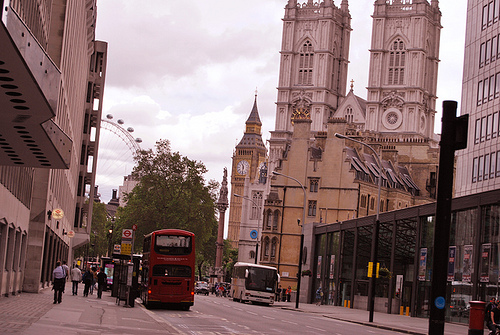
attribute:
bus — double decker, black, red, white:
[139, 227, 198, 316]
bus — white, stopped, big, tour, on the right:
[228, 260, 283, 311]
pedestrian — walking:
[49, 260, 67, 305]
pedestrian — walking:
[95, 265, 109, 299]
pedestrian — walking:
[69, 261, 83, 296]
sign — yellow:
[364, 258, 382, 281]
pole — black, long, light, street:
[366, 220, 385, 326]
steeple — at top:
[349, 78, 356, 90]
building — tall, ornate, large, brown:
[232, 1, 465, 301]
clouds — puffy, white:
[145, 57, 269, 114]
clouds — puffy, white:
[96, 83, 170, 124]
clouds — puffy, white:
[86, 106, 276, 190]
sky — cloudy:
[79, 0, 471, 240]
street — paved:
[107, 276, 424, 334]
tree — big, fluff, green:
[110, 139, 231, 291]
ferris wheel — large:
[81, 110, 157, 243]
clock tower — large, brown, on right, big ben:
[225, 84, 267, 276]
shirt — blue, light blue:
[51, 267, 66, 282]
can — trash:
[466, 300, 488, 334]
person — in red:
[284, 282, 293, 302]